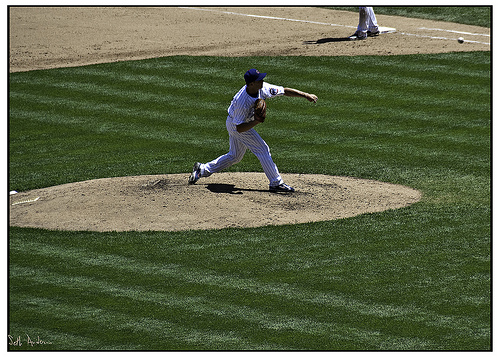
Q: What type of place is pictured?
A: It is a field.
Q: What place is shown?
A: It is a field.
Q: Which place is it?
A: It is a field.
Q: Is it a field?
A: Yes, it is a field.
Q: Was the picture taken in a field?
A: Yes, it was taken in a field.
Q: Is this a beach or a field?
A: It is a field.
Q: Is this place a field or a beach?
A: It is a field.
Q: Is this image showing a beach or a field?
A: It is showing a field.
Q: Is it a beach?
A: No, it is a field.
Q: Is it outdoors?
A: Yes, it is outdoors.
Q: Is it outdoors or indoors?
A: It is outdoors.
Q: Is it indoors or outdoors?
A: It is outdoors.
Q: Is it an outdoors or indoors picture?
A: It is outdoors.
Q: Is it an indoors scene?
A: No, it is outdoors.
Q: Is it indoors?
A: No, it is outdoors.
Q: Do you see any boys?
A: No, there are no boys.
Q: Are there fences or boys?
A: No, there are no boys or fences.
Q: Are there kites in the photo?
A: No, there are no kites.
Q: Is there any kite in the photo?
A: No, there are no kites.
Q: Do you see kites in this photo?
A: No, there are no kites.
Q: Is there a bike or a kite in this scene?
A: No, there are no kites or bikes.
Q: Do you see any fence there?
A: No, there are no fences.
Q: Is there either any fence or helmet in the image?
A: No, there are no fences or helmets.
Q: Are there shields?
A: No, there are no shields.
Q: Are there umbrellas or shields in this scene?
A: No, there are no shields or umbrellas.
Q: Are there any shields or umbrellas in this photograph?
A: No, there are no shields or umbrellas.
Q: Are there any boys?
A: No, there are no boys.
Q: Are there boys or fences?
A: No, there are no boys or fences.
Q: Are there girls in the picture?
A: No, there are no girls.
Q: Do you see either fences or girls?
A: No, there are no girls or fences.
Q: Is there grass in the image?
A: Yes, there is grass.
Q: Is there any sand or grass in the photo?
A: Yes, there is grass.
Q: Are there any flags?
A: No, there are no flags.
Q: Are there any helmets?
A: No, there are no helmets.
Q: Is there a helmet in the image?
A: No, there are no helmets.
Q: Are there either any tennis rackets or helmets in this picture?
A: No, there are no helmets or tennis rackets.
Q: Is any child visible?
A: No, there are no children.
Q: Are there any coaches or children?
A: No, there are no children or coaches.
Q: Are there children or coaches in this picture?
A: No, there are no children or coaches.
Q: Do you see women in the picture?
A: No, there are no women.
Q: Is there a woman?
A: No, there are no women.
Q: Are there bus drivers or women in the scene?
A: No, there are no women or bus drivers.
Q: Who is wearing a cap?
A: The player is wearing a cap.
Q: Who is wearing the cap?
A: The player is wearing a cap.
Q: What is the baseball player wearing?
A: The player is wearing a cap.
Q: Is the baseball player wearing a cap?
A: Yes, the player is wearing a cap.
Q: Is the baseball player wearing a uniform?
A: No, the player is wearing a cap.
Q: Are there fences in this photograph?
A: No, there are no fences.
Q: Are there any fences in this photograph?
A: No, there are no fences.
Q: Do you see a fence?
A: No, there are no fences.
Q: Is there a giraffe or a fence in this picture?
A: No, there are no fences or giraffes.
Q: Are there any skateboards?
A: No, there are no skateboards.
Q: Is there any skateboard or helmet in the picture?
A: No, there are no skateboards or helmets.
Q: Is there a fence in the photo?
A: No, there are no fences.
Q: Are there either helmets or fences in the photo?
A: No, there are no fences or helmets.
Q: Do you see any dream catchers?
A: No, there are no dream catchers.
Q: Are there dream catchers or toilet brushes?
A: No, there are no dream catchers or toilet brushes.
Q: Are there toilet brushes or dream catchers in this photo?
A: No, there are no dream catchers or toilet brushes.